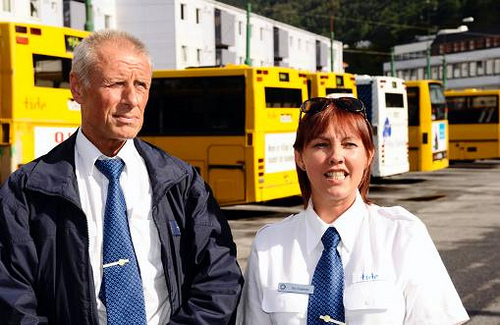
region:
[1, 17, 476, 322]
a man and a woman in front yellow buses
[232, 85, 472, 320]
a woman wearing white shirt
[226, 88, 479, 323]
a woman wearing a tie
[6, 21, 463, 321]
two persons wearing the same color of tie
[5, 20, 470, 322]
two people wearing blue ties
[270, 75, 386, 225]
a pair of glasses on head of woman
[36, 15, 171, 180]
man has gray hair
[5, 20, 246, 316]
man has black jacket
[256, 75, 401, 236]
woman is showing her teeth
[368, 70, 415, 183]
a white bus in middle of yellow buses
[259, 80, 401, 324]
Woman wearing a tie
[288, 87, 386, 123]
Glasses on top of head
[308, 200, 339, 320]
The tie is blue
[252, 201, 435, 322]
Her shirt is white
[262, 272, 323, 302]
Name tag on her shirt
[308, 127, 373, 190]
Woman clenching her teeth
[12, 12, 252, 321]
Man wearing a jacket and tie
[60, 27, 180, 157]
The man has short hair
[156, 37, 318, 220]
Yellow bus in background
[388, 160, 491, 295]
The pavement is wet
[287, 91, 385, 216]
woman wearing sunglasses on top of her head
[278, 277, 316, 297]
employee name tag on shirt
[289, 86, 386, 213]
woman with short red hair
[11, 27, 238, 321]
man wearing blue jacket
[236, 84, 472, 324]
woman wearing white short sleeve shirt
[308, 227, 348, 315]
blue and white tie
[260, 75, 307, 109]
rear window of bus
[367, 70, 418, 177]
back of white bus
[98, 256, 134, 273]
silver tie bar on tie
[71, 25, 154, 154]
man with short gray hair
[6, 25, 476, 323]
a man and a woman beside each other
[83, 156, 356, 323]
the ties are blue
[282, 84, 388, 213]
the woman is smiling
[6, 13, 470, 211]
a row of buses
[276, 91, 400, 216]
brown sunglasses on the woman's head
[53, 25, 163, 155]
the man has short gray hair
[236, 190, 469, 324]
the woman's shirt is white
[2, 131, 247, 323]
the man is wearing a dark blue jacket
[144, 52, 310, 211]
the bus is yellow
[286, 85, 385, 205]
the woman has auburn colored hair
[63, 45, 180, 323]
this is a man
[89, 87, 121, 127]
the man is light skinned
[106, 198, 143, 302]
this is a neck tie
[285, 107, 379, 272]
this is a lady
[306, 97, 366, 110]
this is a spectacle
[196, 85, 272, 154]
this is a bus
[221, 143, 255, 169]
the bus is yellow in color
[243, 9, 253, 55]
this is a pole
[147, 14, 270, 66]
this is a building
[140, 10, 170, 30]
the wall is white in color